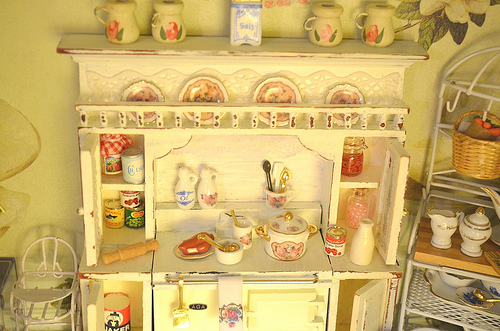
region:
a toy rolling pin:
[101, 228, 159, 270]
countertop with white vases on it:
[70, 1, 421, 56]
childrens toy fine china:
[77, 64, 401, 126]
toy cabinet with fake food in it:
[85, 137, 152, 275]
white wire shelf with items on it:
[405, 47, 497, 329]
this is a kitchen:
[41, 45, 415, 329]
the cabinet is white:
[90, 84, 295, 212]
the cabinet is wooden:
[144, 37, 336, 285]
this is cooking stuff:
[162, 217, 343, 288]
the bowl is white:
[212, 237, 249, 265]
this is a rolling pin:
[98, 230, 170, 254]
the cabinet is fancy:
[101, 73, 392, 204]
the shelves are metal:
[414, 37, 496, 217]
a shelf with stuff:
[67, 109, 399, 326]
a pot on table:
[283, 202, 319, 279]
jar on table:
[347, 130, 360, 163]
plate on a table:
[329, 62, 360, 147]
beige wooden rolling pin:
[98, 235, 161, 266]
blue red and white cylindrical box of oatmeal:
[96, 290, 133, 330]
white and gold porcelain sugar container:
[456, 205, 494, 260]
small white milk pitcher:
[346, 212, 378, 268]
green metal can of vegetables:
[121, 200, 150, 230]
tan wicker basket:
[450, 105, 498, 182]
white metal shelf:
[393, 39, 499, 329]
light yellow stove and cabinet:
[50, 23, 435, 329]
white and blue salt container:
[223, 1, 265, 48]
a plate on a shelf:
[125, 83, 152, 128]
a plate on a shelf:
[192, 68, 226, 112]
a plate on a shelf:
[257, 65, 297, 129]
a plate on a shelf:
[319, 67, 373, 143]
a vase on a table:
[350, 218, 380, 265]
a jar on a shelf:
[337, 133, 365, 171]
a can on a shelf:
[127, 200, 162, 266]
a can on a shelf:
[104, 202, 131, 233]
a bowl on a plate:
[214, 233, 253, 300]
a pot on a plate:
[275, 208, 320, 299]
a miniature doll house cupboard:
[55, 30, 432, 329]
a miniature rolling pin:
[98, 236, 158, 263]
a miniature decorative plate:
[119, 80, 164, 125]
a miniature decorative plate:
[179, 76, 228, 124]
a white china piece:
[253, 203, 322, 270]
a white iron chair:
[8, 228, 76, 329]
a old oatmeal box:
[104, 284, 144, 329]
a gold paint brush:
[167, 268, 197, 330]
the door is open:
[321, 272, 412, 329]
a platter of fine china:
[401, 271, 499, 322]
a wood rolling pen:
[91, 228, 158, 278]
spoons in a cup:
[257, 156, 304, 213]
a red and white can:
[316, 219, 350, 261]